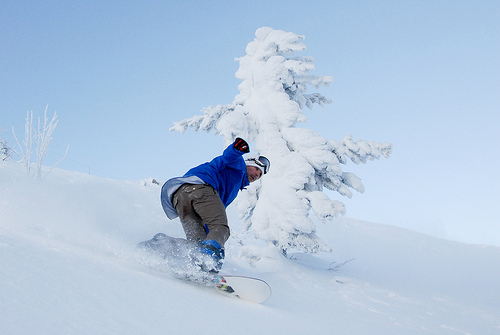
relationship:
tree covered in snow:
[170, 23, 391, 261] [269, 69, 326, 181]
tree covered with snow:
[170, 23, 391, 261] [1, 17, 496, 332]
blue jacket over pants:
[168, 144, 253, 202] [170, 182, 231, 255]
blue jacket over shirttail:
[168, 144, 253, 202] [151, 172, 201, 207]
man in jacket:
[151, 134, 276, 276] [187, 143, 253, 206]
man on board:
[159, 137, 271, 274] [136, 233, 275, 306]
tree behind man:
[170, 23, 391, 261] [161, 137, 271, 271]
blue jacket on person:
[159, 136, 249, 221] [127, 108, 305, 293]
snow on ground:
[2, 155, 495, 332] [1, 150, 496, 333]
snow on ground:
[1, 17, 496, 332] [1, 150, 496, 333]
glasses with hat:
[244, 155, 271, 175] [244, 153, 267, 179]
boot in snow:
[195, 238, 226, 286] [2, 155, 495, 332]